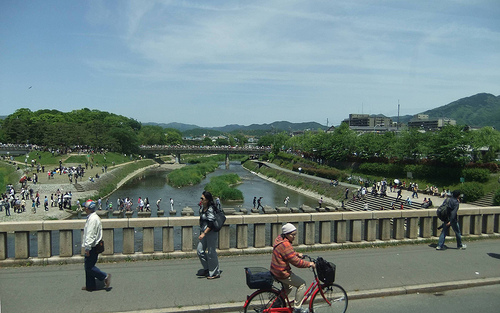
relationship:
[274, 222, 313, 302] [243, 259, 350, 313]
boy on bike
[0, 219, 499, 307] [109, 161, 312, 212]
bride over water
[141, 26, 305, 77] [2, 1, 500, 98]
clouds in sky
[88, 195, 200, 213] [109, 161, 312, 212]
people crossing water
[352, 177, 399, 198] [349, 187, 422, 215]
people on steps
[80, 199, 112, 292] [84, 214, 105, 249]
man wearing shirt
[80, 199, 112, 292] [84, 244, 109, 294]
man wearing pants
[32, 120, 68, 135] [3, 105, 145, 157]
leaves on trees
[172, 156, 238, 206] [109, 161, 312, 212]
trees in water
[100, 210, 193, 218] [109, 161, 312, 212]
stones in water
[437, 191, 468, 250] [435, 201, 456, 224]
man has backpack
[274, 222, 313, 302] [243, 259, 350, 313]
boy riding bike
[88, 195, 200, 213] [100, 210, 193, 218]
people walking on stones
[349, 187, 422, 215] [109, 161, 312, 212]
steps from water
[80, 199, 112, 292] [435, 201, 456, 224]
man carrying backpack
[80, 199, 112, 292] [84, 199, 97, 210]
man wearing cap